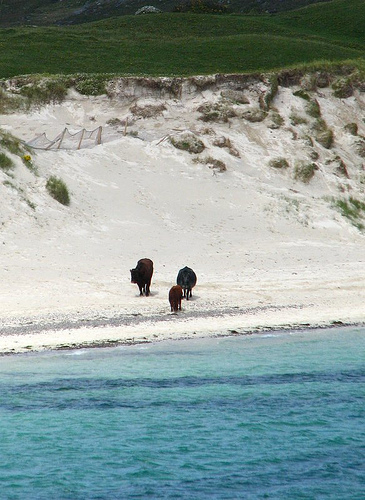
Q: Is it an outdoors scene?
A: Yes, it is outdoors.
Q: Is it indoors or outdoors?
A: It is outdoors.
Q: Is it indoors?
A: No, it is outdoors.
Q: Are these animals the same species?
A: Yes, all the animals are bison.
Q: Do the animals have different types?
A: No, all the animals are bison.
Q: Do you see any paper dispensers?
A: No, there are no paper dispensers.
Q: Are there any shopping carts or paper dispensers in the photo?
A: No, there are no paper dispensers or shopping carts.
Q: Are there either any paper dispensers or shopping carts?
A: No, there are no paper dispensers or shopping carts.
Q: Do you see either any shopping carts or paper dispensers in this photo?
A: No, there are no paper dispensers or shopping carts.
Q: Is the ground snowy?
A: Yes, the ground is snowy.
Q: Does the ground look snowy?
A: Yes, the ground is snowy.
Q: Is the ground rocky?
A: No, the ground is snowy.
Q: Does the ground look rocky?
A: No, the ground is snowy.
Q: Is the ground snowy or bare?
A: The ground is snowy.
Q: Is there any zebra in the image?
A: No, there are no zebras.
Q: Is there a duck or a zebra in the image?
A: No, there are no zebras or ducks.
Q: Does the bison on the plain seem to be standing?
A: Yes, the bison is standing.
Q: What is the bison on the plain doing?
A: The bison is standing.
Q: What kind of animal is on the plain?
A: The animal is a bison.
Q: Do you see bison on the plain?
A: Yes, there is a bison on the plain.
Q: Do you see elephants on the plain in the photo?
A: No, there is a bison on the plain.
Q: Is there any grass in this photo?
A: Yes, there is grass.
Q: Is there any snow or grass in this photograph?
A: Yes, there is grass.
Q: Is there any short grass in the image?
A: Yes, there is short grass.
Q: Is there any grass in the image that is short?
A: Yes, there is grass that is short.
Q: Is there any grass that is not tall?
A: Yes, there is short grass.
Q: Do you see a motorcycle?
A: No, there are no motorcycles.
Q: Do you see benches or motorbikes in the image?
A: No, there are no motorbikes or benches.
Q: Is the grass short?
A: Yes, the grass is short.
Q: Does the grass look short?
A: Yes, the grass is short.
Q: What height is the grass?
A: The grass is short.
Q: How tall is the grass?
A: The grass is short.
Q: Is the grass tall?
A: No, the grass is short.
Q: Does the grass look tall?
A: No, the grass is short.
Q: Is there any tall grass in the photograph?
A: No, there is grass but it is short.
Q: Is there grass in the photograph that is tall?
A: No, there is grass but it is short.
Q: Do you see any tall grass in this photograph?
A: No, there is grass but it is short.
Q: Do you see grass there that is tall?
A: No, there is grass but it is short.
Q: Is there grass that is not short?
A: No, there is grass but it is short.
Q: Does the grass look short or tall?
A: The grass is short.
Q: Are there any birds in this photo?
A: No, there are no birds.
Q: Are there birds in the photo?
A: No, there are no birds.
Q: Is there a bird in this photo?
A: No, there are no birds.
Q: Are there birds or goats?
A: No, there are no birds or goats.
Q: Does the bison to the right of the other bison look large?
A: Yes, the bison is large.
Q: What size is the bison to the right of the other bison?
A: The bison is large.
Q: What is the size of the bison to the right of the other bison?
A: The bison is large.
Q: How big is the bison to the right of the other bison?
A: The bison is large.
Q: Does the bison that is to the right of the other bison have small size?
A: No, the bison is large.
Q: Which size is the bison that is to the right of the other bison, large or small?
A: The bison is large.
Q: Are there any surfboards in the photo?
A: No, there are no surfboards.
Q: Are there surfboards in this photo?
A: No, there are no surfboards.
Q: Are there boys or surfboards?
A: No, there are no surfboards or boys.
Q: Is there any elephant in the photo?
A: No, there are no elephants.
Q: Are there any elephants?
A: No, there are no elephants.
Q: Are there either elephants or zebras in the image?
A: No, there are no elephants or zebras.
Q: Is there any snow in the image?
A: Yes, there is snow.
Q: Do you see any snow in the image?
A: Yes, there is snow.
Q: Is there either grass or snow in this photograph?
A: Yes, there is snow.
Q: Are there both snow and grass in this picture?
A: Yes, there are both snow and grass.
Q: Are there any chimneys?
A: No, there are no chimneys.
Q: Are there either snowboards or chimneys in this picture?
A: No, there are no chimneys or snowboards.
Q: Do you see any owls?
A: No, there are no owls.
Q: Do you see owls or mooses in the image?
A: No, there are no owls or mooses.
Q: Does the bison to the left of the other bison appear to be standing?
A: Yes, the bison is standing.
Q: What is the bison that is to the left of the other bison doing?
A: The bison is standing.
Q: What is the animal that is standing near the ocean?
A: The animal is a bison.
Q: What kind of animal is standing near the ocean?
A: The animal is a bison.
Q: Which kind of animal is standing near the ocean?
A: The animal is a bison.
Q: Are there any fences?
A: Yes, there is a fence.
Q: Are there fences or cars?
A: Yes, there is a fence.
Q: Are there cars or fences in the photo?
A: Yes, there is a fence.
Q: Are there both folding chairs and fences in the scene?
A: No, there is a fence but no folding chairs.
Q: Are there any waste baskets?
A: No, there are no waste baskets.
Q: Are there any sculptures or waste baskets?
A: No, there are no waste baskets or sculptures.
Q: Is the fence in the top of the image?
A: Yes, the fence is in the top of the image.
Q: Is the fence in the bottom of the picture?
A: No, the fence is in the top of the image.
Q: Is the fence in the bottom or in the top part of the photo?
A: The fence is in the top of the image.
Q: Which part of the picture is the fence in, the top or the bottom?
A: The fence is in the top of the image.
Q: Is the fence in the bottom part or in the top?
A: The fence is in the top of the image.